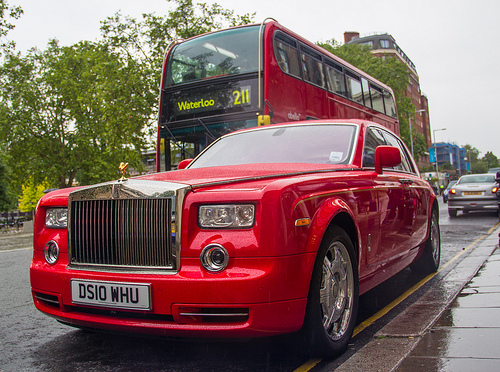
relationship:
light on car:
[42, 200, 69, 232] [4, 126, 473, 337]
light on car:
[205, 205, 260, 230] [4, 126, 473, 337]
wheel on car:
[417, 199, 449, 277] [47, 120, 402, 347]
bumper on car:
[29, 264, 309, 334] [29, 117, 441, 352]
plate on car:
[54, 271, 155, 319] [21, 133, 441, 287]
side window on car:
[353, 127, 420, 179] [29, 117, 441, 352]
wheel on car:
[283, 222, 362, 355] [29, 117, 441, 352]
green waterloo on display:
[161, 88, 227, 122] [160, 74, 263, 124]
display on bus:
[160, 74, 263, 124] [151, 12, 412, 183]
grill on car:
[66, 174, 196, 272] [29, 117, 441, 352]